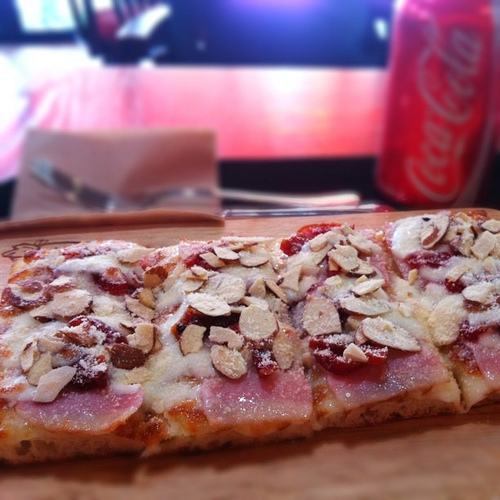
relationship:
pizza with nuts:
[14, 246, 500, 405] [186, 294, 235, 324]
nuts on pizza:
[186, 294, 235, 324] [14, 246, 500, 405]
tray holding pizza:
[247, 441, 427, 484] [14, 246, 500, 405]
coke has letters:
[394, 6, 484, 203] [423, 28, 483, 122]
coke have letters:
[394, 6, 484, 203] [423, 28, 483, 122]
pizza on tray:
[14, 246, 500, 405] [247, 441, 427, 484]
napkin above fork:
[104, 145, 179, 166] [36, 158, 354, 208]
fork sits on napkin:
[36, 158, 354, 208] [104, 145, 179, 166]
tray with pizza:
[247, 441, 427, 484] [14, 246, 500, 405]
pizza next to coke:
[14, 246, 500, 405] [394, 6, 484, 203]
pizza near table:
[14, 246, 500, 405] [174, 64, 279, 116]